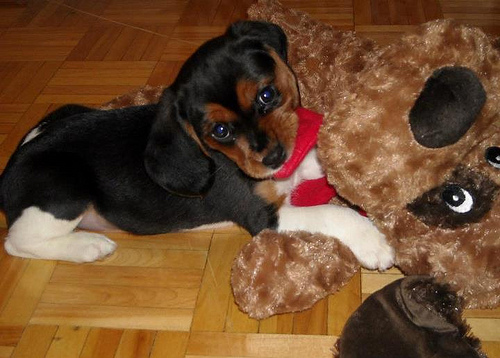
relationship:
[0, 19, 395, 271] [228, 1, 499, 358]
puppy next to stuffed dog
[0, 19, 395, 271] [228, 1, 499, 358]
puppy playing with stuffed dog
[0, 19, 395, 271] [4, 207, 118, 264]
puppy has foot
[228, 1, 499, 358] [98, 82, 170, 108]
stuffed dog has foot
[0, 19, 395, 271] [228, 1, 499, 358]
puppy cuddling stuffed dog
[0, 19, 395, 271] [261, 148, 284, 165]
puppy has nose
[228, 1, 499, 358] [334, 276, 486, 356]
stuffed dog has ear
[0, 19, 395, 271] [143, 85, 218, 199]
puppy has ear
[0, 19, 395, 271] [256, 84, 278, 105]
puppy has eye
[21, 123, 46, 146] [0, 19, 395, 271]
spot on puppy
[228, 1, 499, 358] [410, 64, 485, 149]
stuffed dog has nose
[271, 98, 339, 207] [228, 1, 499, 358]
bow on stuffed dog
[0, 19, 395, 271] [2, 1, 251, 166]
puppy laying on floor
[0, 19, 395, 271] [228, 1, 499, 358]
puppy laying on stuffed dog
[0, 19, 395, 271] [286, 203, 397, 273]
puppy has paw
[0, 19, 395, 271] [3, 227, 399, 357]
puppy laying on floor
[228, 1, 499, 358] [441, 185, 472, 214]
stuffed dog has eye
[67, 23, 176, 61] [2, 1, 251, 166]
square on floor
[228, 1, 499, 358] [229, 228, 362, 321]
stuffed dog has arm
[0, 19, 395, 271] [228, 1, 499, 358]
puppy sitting next to stuffed dog